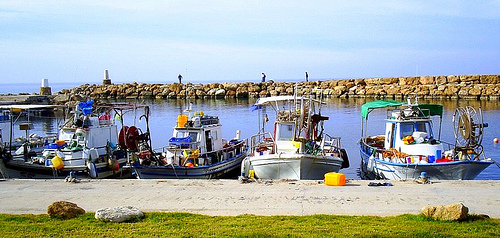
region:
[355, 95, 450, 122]
this canopy is green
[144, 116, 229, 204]
this boat is blue and white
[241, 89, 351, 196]
this boat is white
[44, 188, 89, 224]
this rock is brown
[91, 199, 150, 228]
this rock is white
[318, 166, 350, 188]
this plastic jug is yellow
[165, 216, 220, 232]
the grass is yellowish green in color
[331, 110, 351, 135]
the water is blue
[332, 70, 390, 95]
the rock barrier is made up of big bolders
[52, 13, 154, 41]
the sky is light blue and white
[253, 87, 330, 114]
the roof of a boat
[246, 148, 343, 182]
the bow of a boat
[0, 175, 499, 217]
a gray sandy beach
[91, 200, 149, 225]
a gray rock on the ground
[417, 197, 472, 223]
a brown rock on the grass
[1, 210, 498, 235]
a patch of green grass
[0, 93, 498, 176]
a small calm cove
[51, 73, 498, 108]
a small rock wall in the water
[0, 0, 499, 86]
a blue sky overhead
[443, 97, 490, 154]
a large metal fan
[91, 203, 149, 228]
a gray rock on the grass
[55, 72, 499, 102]
a rock wall in the water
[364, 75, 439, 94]
the rocks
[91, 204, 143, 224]
white rock on the grass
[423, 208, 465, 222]
brown rock on the grass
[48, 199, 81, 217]
brown rock on the grass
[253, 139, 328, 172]
a white boat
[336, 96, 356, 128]
the water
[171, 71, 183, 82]
a person standing on the rocks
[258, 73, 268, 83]
a person standing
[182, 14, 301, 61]
the sky is light blue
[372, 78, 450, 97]
the rocks are brown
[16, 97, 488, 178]
a line of boats docked at the marina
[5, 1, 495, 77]
the bright blue sky with a few clouds in it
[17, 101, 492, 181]
the lake the boats are sitting on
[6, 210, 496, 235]
some grass on the ground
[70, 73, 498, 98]
the wall made of rocks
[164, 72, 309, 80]
people standing on top of the wall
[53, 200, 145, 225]
some rocks on the ground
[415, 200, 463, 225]
another rock on the ground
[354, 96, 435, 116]
the green cover on one of the boats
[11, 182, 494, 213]
a sidewalk for people to walk on